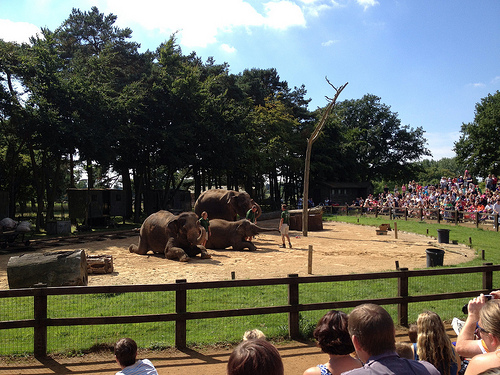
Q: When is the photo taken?
A: Daytime.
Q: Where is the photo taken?
A: At the zoo.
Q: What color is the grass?
A: Green.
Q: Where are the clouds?
A: In the sky.